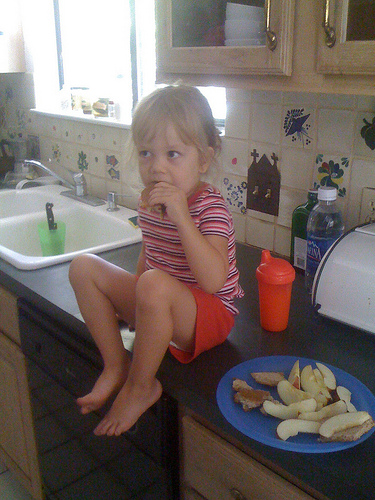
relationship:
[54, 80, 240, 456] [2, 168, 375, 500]
girl on counter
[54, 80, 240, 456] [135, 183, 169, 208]
girl has cookie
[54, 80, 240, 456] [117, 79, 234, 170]
girl has hair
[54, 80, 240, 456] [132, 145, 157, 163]
girl has eye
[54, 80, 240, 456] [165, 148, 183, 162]
girl has eye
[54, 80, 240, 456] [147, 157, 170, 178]
girl has nose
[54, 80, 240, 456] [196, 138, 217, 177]
girl has ear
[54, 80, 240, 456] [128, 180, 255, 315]
girl wears shirt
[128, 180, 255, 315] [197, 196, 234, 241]
shirt has sleeve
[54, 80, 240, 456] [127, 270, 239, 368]
girl wears shorts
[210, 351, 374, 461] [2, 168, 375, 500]
plate on counter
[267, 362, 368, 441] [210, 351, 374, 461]
apple on plate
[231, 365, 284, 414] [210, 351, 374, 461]
bread on plate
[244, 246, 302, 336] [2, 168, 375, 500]
cup on counter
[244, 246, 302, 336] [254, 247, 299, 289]
cup has lid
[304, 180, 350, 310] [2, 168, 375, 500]
bottle on counter